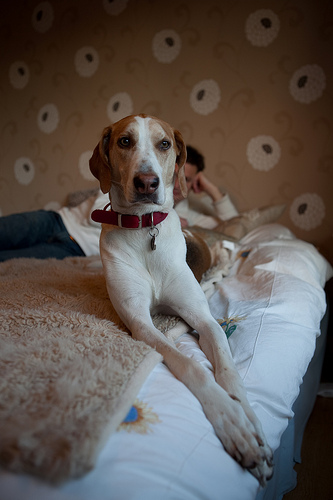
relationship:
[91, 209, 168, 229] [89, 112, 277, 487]
collar around dog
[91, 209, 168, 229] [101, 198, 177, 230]
collar around neck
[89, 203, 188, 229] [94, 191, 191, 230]
collar around neck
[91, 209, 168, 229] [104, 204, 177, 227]
collar around neck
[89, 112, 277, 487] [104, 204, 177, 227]
dog has neck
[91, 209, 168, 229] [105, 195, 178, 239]
collar around neck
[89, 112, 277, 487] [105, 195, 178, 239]
dog has neck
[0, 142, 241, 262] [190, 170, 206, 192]
man has fist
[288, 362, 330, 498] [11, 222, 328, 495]
carpet on top of bed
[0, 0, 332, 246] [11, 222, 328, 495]
wall behind bed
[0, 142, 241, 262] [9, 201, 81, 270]
man wearing jeans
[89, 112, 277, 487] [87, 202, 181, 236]
dog wearing collar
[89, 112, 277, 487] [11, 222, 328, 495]
dog laying on bed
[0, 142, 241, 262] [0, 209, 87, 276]
man wearing jeans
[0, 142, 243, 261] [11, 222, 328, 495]
man on bed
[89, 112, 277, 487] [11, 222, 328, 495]
dog on bed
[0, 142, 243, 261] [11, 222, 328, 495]
man laying on bed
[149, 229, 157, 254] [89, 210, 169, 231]
tag on collar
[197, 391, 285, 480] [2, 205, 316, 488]
paws hanging off bed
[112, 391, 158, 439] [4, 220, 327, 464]
flower on comforter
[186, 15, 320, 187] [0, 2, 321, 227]
wallpaper on wall